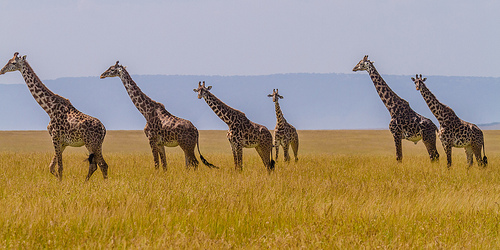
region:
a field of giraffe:
[1, 46, 498, 187]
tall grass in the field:
[8, 173, 468, 248]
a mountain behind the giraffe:
[3, 74, 496, 132]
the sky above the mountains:
[4, 3, 483, 71]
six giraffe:
[5, 52, 489, 162]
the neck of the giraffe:
[121, 78, 153, 115]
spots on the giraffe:
[51, 105, 72, 135]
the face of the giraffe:
[192, 82, 213, 97]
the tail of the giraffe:
[197, 137, 218, 165]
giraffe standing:
[6, 47, 488, 217]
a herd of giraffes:
[1, 50, 493, 184]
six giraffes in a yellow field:
[2, 50, 491, 185]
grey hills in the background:
[3, 67, 499, 132]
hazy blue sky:
[0, 1, 499, 83]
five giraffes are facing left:
[1, 49, 489, 182]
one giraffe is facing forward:
[266, 84, 303, 167]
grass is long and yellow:
[3, 129, 497, 249]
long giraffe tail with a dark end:
[191, 130, 222, 171]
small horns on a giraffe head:
[197, 78, 207, 89]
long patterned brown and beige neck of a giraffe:
[18, 63, 62, 117]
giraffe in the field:
[2, 30, 113, 177]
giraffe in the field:
[107, 71, 212, 174]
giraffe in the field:
[196, 89, 268, 177]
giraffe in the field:
[267, 68, 304, 165]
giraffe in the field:
[334, 57, 439, 175]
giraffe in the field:
[412, 77, 489, 172]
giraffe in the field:
[119, 83, 205, 178]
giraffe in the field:
[260, 78, 297, 160]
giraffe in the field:
[0, 45, 100, 175]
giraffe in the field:
[270, 85, 299, 175]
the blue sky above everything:
[2, 1, 499, 77]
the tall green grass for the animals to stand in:
[1, 155, 499, 249]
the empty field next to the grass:
[2, 131, 499, 158]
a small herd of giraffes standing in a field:
[5, 53, 490, 175]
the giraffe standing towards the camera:
[265, 87, 300, 162]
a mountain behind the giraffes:
[1, 78, 498, 130]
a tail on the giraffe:
[196, 139, 218, 168]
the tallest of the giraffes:
[349, 56, 436, 158]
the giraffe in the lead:
[1, 53, 108, 174]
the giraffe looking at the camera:
[406, 73, 428, 91]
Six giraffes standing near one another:
[3, 47, 494, 174]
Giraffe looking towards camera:
[263, 89, 314, 163]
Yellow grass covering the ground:
[3, 146, 498, 248]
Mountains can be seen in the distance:
[0, 79, 497, 131]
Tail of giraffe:
[195, 134, 220, 174]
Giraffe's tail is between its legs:
[73, 139, 101, 170]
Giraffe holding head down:
[189, 80, 279, 178]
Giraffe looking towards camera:
[412, 64, 497, 174]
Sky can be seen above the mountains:
[0, 3, 498, 75]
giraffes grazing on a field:
[1, 52, 498, 249]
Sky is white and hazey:
[0, 0, 499, 84]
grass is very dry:
[1, 130, 499, 247]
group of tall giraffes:
[1, 50, 499, 180]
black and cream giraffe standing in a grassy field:
[412, 73, 490, 169]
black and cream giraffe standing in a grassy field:
[349, 53, 439, 163]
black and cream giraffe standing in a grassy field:
[268, 86, 302, 164]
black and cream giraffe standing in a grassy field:
[193, 76, 277, 176]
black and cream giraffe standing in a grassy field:
[102, 64, 221, 173]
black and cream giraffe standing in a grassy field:
[1, 53, 110, 179]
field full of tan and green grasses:
[2, 130, 498, 249]